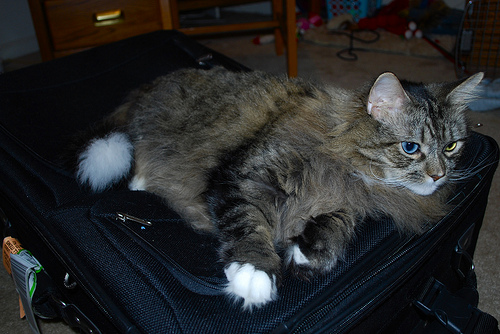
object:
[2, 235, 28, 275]
label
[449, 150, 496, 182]
whiskers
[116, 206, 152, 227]
clasp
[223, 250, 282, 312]
paw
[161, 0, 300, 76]
desk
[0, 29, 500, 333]
suitcase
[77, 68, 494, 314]
cat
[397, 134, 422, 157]
eye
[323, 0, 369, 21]
crate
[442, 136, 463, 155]
eye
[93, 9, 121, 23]
brass handle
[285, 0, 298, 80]
leg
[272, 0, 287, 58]
leg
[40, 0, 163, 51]
drawer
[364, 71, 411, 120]
ear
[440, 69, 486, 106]
ear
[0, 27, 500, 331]
ground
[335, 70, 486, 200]
head